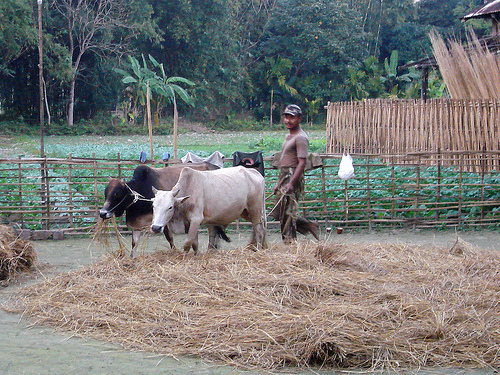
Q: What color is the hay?
A: Brown.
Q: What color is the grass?
A: Green.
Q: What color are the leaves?
A: Green.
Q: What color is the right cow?
A: Tan.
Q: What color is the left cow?
A: Brown.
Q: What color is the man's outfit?
A: Brown.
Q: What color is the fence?
A: Brown.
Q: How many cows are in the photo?
A: 2.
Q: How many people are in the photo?
A: One.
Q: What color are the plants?
A: Green.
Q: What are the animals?
A: Cows.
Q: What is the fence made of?
A: Sticks.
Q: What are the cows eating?
A: Hay.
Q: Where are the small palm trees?
A: In the field.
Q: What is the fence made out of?
A: Wood.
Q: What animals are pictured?
A: Cows.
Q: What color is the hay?
A: Brown.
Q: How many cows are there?
A: Two.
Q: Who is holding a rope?
A: The man.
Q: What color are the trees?
A: Green.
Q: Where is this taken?
A: On a farm.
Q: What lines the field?
A: A forest.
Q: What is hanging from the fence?
A: A white plastic bag.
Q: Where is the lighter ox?
A: Beside the dark ox.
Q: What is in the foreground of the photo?
A: Hay.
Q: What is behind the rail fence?
A: A garden.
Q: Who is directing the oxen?
A: A man.